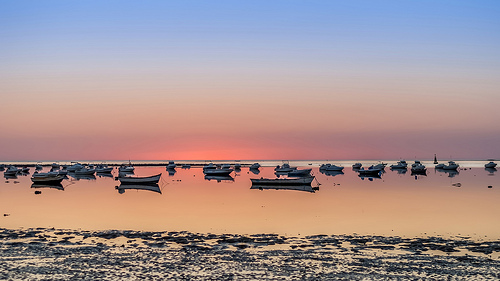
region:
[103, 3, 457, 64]
this is the sky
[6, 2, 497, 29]
the sky is blue in color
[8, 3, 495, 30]
the sky is clear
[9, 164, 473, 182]
these are several boats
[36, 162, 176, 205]
the boats are on the water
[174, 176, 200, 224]
this is an ocean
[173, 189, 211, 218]
this is the ocean water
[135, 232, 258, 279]
this is the beach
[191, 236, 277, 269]
the beach is sandy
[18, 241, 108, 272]
the ground has tracks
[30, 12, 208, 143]
blue, purple and orange evening sky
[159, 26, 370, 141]
blue, purple and orange evening sky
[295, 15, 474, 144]
blue, purple and orange evening sky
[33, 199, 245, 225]
reflection on wet beach sand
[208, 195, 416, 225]
reflection on wet beach sand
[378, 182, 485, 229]
reflection on wet beach sand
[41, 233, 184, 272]
wet gray beach sand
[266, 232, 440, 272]
wet gray beach sand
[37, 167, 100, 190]
boats on sand at beach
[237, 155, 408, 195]
boats on sand at beach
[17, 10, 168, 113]
blue, orange and purple evening sky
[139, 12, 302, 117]
blue, orange and purple evening sky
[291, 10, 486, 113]
blue, orange and purple evening sky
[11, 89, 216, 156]
blue, orange and purple evening sky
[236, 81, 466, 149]
blue, orange and purple evening sky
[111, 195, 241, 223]
reflection on beach sand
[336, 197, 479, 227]
reflection on beach sand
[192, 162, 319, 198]
boats in water near beach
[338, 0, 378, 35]
part of the sky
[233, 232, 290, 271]
part of the shore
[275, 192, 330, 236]
part of a water surface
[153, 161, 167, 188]
edge of a boat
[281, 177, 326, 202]
reflection of a boat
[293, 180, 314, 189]
bottom of a boat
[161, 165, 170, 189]
part of a string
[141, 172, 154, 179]
edge of a boat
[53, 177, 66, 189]
part of a shadow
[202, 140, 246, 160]
part of some rays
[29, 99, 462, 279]
The sun is going down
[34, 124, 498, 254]
There are boats in the water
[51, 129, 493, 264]
There are many boats in the water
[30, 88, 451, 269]
There is no one in the photo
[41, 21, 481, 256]
The sky is red and blue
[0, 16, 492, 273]
There are no clouds in the sjy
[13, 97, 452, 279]
The boats leave a shadow on the water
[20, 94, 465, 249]
There are no birds flying in the photo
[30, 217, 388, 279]
There is land near the water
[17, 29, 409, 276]
There is land under the blue sky